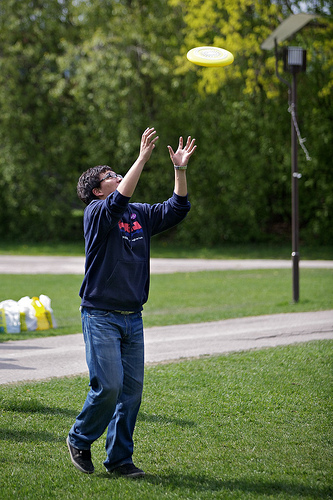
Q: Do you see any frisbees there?
A: Yes, there is a frisbee.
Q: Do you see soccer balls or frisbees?
A: Yes, there is a frisbee.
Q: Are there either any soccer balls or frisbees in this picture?
A: Yes, there is a frisbee.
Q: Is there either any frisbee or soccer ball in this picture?
A: Yes, there is a frisbee.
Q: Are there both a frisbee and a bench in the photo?
A: No, there is a frisbee but no benches.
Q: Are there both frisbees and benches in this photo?
A: No, there is a frisbee but no benches.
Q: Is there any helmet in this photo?
A: No, there are no helmets.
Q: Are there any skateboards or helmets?
A: No, there are no helmets or skateboards.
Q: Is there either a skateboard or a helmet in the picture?
A: No, there are no helmets or skateboards.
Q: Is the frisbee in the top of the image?
A: Yes, the frisbee is in the top of the image.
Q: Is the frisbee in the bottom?
A: No, the frisbee is in the top of the image.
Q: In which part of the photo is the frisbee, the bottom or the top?
A: The frisbee is in the top of the image.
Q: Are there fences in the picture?
A: No, there are no fences.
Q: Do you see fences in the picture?
A: No, there are no fences.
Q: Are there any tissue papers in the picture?
A: No, there are no tissue papers.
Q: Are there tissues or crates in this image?
A: No, there are no tissues or crates.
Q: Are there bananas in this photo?
A: No, there are no bananas.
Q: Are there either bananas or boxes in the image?
A: No, there are no bananas or boxes.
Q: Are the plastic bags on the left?
A: Yes, the bags are on the left of the image.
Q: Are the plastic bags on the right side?
A: No, the bags are on the left of the image.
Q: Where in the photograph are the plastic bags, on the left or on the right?
A: The bags are on the left of the image.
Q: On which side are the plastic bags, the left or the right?
A: The bags are on the left of the image.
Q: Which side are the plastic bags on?
A: The bags are on the left of the image.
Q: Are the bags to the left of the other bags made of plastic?
A: Yes, the bags are made of plastic.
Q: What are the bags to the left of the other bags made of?
A: The bags are made of plastic.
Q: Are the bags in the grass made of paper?
A: No, the bags are made of plastic.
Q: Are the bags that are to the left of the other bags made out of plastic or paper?
A: The bags are made of plastic.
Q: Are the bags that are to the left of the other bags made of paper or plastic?
A: The bags are made of plastic.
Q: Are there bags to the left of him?
A: Yes, there are bags to the left of the man.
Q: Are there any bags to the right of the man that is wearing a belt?
A: No, the bags are to the left of the man.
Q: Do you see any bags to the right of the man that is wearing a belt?
A: No, the bags are to the left of the man.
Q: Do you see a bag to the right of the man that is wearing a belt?
A: No, the bags are to the left of the man.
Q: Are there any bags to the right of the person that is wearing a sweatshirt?
A: No, the bags are to the left of the man.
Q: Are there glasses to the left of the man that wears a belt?
A: No, there are bags to the left of the man.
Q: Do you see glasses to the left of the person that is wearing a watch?
A: No, there are bags to the left of the man.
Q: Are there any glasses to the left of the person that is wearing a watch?
A: No, there are bags to the left of the man.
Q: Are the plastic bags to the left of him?
A: Yes, the bags are to the left of a man.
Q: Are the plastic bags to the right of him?
A: No, the bags are to the left of the man.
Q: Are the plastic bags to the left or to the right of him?
A: The bags are to the left of the man.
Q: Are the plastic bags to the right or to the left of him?
A: The bags are to the left of the man.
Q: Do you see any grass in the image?
A: Yes, there is grass.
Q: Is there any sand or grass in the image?
A: Yes, there is grass.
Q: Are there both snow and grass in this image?
A: No, there is grass but no snow.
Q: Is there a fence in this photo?
A: No, there are no fences.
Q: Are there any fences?
A: No, there are no fences.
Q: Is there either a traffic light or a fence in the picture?
A: No, there are no fences or traffic lights.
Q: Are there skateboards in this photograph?
A: No, there are no skateboards.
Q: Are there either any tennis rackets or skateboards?
A: No, there are no skateboards or tennis rackets.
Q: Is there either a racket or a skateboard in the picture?
A: No, there are no skateboards or rackets.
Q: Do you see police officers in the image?
A: No, there are no police officers.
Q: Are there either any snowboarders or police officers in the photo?
A: No, there are no police officers or snowboarders.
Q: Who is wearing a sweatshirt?
A: The man is wearing a sweatshirt.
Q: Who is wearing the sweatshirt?
A: The man is wearing a sweatshirt.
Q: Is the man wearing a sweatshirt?
A: Yes, the man is wearing a sweatshirt.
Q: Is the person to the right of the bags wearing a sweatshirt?
A: Yes, the man is wearing a sweatshirt.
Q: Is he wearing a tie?
A: No, the man is wearing a sweatshirt.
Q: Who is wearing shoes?
A: The man is wearing shoes.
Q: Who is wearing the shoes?
A: The man is wearing shoes.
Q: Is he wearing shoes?
A: Yes, the man is wearing shoes.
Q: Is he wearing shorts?
A: No, the man is wearing shoes.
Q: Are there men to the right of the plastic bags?
A: Yes, there is a man to the right of the bags.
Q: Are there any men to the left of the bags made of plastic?
A: No, the man is to the right of the bags.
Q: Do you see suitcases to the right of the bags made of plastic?
A: No, there is a man to the right of the bags.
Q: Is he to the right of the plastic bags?
A: Yes, the man is to the right of the bags.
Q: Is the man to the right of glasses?
A: No, the man is to the right of the bags.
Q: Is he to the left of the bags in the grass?
A: No, the man is to the right of the bags.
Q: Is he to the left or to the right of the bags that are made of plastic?
A: The man is to the right of the bags.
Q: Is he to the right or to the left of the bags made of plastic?
A: The man is to the right of the bags.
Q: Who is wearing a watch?
A: The man is wearing a watch.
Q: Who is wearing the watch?
A: The man is wearing a watch.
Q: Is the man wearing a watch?
A: Yes, the man is wearing a watch.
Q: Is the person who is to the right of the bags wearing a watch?
A: Yes, the man is wearing a watch.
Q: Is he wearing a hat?
A: No, the man is wearing a watch.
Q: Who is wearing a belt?
A: The man is wearing a belt.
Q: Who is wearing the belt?
A: The man is wearing a belt.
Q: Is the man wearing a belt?
A: Yes, the man is wearing a belt.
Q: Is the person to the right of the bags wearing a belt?
A: Yes, the man is wearing a belt.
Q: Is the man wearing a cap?
A: No, the man is wearing a belt.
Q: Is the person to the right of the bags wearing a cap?
A: No, the man is wearing a belt.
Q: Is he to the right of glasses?
A: No, the man is to the right of the bags.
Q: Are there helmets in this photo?
A: No, there are no helmets.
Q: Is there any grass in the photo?
A: Yes, there is grass.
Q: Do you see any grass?
A: Yes, there is grass.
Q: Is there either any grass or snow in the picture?
A: Yes, there is grass.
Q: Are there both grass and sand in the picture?
A: No, there is grass but no sand.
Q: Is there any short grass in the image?
A: Yes, there is short grass.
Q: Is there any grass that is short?
A: Yes, there is grass that is short.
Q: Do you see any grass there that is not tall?
A: Yes, there is short grass.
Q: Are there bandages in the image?
A: No, there are no bandages.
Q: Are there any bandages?
A: No, there are no bandages.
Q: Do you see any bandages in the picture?
A: No, there are no bandages.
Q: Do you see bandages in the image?
A: No, there are no bandages.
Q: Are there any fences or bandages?
A: No, there are no bandages or fences.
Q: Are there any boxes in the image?
A: No, there are no boxes.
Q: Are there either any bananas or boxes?
A: No, there are no boxes or bananas.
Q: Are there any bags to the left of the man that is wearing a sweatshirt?
A: Yes, there are bags to the left of the man.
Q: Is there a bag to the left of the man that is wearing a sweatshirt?
A: Yes, there are bags to the left of the man.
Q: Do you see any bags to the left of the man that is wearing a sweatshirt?
A: Yes, there are bags to the left of the man.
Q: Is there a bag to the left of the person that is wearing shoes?
A: Yes, there are bags to the left of the man.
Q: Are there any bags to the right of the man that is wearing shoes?
A: No, the bags are to the left of the man.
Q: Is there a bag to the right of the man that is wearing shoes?
A: No, the bags are to the left of the man.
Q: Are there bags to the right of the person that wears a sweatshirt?
A: No, the bags are to the left of the man.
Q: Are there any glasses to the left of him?
A: No, there are bags to the left of the man.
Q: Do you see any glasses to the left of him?
A: No, there are bags to the left of the man.